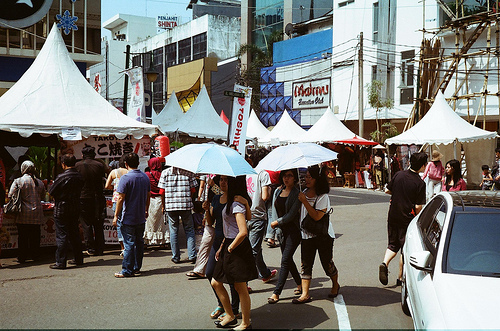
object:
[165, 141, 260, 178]
umbrella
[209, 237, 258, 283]
skirt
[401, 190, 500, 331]
car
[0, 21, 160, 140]
tent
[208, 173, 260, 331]
girl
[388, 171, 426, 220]
tshirt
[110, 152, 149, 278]
people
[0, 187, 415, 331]
street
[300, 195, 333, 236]
bag